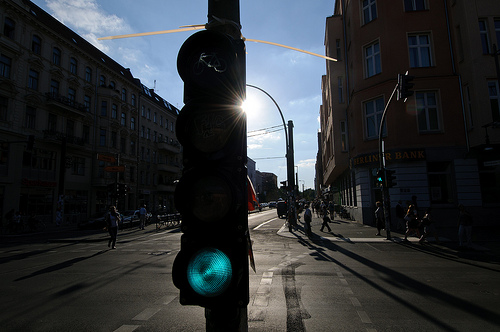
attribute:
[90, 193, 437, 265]
people — walking, close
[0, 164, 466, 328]
road — blue, faded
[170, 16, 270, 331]
light — green, black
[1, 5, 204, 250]
building — wide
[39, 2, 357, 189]
sky — huge, massive, big, white, blue, open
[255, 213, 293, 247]
dash — white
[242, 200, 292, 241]
dash — white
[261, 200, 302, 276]
dash — white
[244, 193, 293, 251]
dash — white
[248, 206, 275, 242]
dash — white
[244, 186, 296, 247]
dash — white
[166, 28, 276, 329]
traffic light — long , black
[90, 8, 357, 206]
sky — light